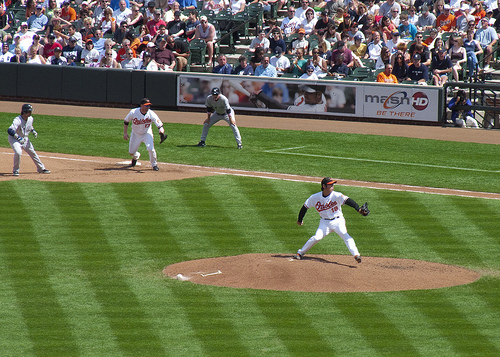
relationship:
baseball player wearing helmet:
[7, 104, 51, 177] [19, 102, 32, 116]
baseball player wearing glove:
[123, 97, 168, 169] [161, 133, 170, 143]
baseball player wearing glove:
[292, 173, 369, 264] [357, 202, 369, 217]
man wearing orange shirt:
[373, 62, 396, 82] [378, 70, 398, 82]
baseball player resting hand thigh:
[195, 88, 242, 149] [202, 110, 219, 130]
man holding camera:
[444, 90, 476, 122] [454, 95, 467, 102]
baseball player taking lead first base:
[7, 104, 51, 177] [0, 142, 197, 187]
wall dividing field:
[9, 55, 484, 125] [0, 55, 490, 130]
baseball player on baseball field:
[292, 173, 369, 264] [0, 98, 497, 355]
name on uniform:
[314, 195, 346, 216] [310, 195, 352, 244]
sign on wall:
[176, 71, 441, 125] [5, 60, 478, 128]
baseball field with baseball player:
[0, 98, 497, 355] [123, 98, 166, 170]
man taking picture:
[447, 91, 479, 129] [5, 6, 469, 346]